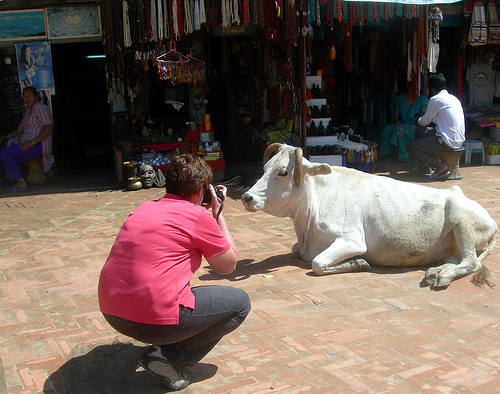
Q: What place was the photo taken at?
A: It was taken at the sidewalk.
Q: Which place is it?
A: It is a sidewalk.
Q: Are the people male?
A: No, they are both male and female.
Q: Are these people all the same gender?
A: No, they are both male and female.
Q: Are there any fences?
A: No, there are no fences.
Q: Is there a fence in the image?
A: No, there are no fences.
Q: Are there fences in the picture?
A: No, there are no fences.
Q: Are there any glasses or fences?
A: No, there are no fences or glasses.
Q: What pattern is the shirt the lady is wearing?
A: The shirt is striped.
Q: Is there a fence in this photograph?
A: No, there are no fences.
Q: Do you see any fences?
A: No, there are no fences.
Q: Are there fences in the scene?
A: No, there are no fences.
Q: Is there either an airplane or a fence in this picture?
A: No, there are no fences or airplanes.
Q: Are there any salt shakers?
A: No, there are no salt shakers.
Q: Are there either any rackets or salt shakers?
A: No, there are no salt shakers or rackets.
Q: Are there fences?
A: No, there are no fences.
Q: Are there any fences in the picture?
A: No, there are no fences.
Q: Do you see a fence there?
A: No, there are no fences.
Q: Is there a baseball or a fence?
A: No, there are no fences or baseballs.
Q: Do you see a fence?
A: No, there are no fences.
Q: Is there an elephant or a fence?
A: No, there are no fences or elephants.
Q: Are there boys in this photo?
A: No, there are no boys.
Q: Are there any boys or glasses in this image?
A: No, there are no boys or glasses.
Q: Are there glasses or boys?
A: No, there are no boys or glasses.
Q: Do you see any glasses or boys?
A: No, there are no boys or glasses.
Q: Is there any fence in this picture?
A: No, there are no fences.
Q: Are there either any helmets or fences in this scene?
A: No, there are no fences or helmets.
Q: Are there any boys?
A: No, there are no boys.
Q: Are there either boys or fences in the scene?
A: No, there are no boys or fences.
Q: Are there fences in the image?
A: No, there are no fences.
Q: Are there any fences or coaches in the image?
A: No, there are no fences or coaches.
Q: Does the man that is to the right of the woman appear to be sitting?
A: Yes, the man is sitting.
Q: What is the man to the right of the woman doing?
A: The man is sitting.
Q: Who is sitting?
A: The man is sitting.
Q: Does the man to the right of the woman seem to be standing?
A: No, the man is sitting.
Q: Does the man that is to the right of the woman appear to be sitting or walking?
A: The man is sitting.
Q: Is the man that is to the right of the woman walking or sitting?
A: The man is sitting.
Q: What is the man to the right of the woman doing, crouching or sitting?
A: The man is sitting.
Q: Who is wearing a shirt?
A: The man is wearing a shirt.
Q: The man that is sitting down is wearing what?
A: The man is wearing a shirt.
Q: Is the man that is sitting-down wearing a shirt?
A: Yes, the man is wearing a shirt.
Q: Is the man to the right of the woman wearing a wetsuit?
A: No, the man is wearing a shirt.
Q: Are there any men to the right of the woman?
A: Yes, there is a man to the right of the woman.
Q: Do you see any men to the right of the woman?
A: Yes, there is a man to the right of the woman.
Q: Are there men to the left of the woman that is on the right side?
A: No, the man is to the right of the woman.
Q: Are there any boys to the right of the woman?
A: No, there is a man to the right of the woman.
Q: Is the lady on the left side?
A: Yes, the lady is on the left of the image.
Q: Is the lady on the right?
A: No, the lady is on the left of the image.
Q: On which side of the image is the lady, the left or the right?
A: The lady is on the left of the image.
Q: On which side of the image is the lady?
A: The lady is on the left of the image.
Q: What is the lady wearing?
A: The lady is wearing a shirt.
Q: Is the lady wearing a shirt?
A: Yes, the lady is wearing a shirt.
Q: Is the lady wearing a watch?
A: No, the lady is wearing a shirt.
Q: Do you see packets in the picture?
A: No, there are no packets.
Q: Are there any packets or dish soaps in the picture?
A: No, there are no packets or dish soaps.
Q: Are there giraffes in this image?
A: No, there are no giraffes.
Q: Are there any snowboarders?
A: No, there are no snowboarders.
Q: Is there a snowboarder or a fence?
A: No, there are no snowboarders or fences.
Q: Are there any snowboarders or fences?
A: No, there are no snowboarders or fences.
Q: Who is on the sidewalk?
A: The man is on the sidewalk.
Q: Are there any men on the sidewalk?
A: Yes, there is a man on the sidewalk.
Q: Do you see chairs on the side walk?
A: No, there is a man on the side walk.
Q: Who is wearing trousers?
A: The man is wearing trousers.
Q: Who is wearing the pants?
A: The man is wearing trousers.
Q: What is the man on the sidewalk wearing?
A: The man is wearing pants.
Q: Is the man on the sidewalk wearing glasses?
A: No, the man is wearing trousers.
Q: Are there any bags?
A: No, there are no bags.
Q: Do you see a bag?
A: No, there are no bags.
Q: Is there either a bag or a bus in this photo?
A: No, there are no bags or buses.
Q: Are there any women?
A: Yes, there is a woman.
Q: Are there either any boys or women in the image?
A: Yes, there is a woman.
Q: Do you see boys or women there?
A: Yes, there is a woman.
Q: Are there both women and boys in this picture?
A: No, there is a woman but no boys.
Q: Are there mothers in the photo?
A: No, there are no mothers.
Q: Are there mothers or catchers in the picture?
A: No, there are no mothers or catchers.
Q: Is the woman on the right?
A: Yes, the woman is on the right of the image.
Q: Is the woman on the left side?
A: No, the woman is on the right of the image.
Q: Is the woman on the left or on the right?
A: The woman is on the right of the image.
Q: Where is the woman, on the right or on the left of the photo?
A: The woman is on the right of the image.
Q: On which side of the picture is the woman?
A: The woman is on the right of the image.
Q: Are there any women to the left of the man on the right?
A: Yes, there is a woman to the left of the man.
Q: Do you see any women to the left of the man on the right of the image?
A: Yes, there is a woman to the left of the man.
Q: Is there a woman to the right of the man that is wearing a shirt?
A: No, the woman is to the left of the man.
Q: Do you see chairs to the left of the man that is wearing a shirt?
A: No, there is a woman to the left of the man.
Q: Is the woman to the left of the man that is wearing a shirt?
A: Yes, the woman is to the left of the man.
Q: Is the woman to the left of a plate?
A: No, the woman is to the left of the man.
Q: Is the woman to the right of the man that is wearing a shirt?
A: No, the woman is to the left of the man.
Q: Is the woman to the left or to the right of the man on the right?
A: The woman is to the left of the man.